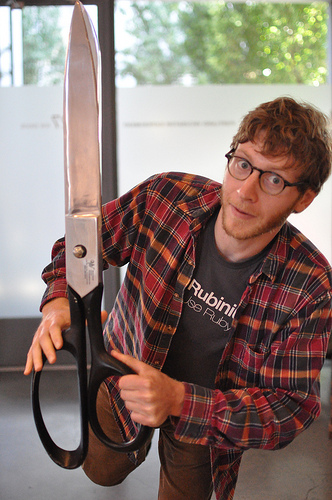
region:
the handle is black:
[26, 276, 155, 472]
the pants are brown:
[81, 368, 227, 497]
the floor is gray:
[10, 445, 60, 486]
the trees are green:
[166, 11, 314, 71]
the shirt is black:
[159, 214, 251, 396]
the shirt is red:
[95, 147, 315, 447]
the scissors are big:
[31, 2, 146, 481]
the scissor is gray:
[50, 7, 119, 305]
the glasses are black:
[210, 141, 311, 215]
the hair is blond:
[234, 78, 330, 179]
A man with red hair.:
[108, 81, 319, 497]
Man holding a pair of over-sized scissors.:
[3, 1, 329, 394]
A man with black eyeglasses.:
[201, 76, 329, 250]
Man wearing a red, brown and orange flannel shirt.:
[61, 80, 330, 424]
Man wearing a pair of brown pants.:
[58, 358, 245, 499]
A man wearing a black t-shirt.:
[115, 151, 331, 422]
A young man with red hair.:
[165, 57, 331, 239]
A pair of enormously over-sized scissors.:
[10, 0, 168, 479]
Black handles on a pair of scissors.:
[24, 273, 174, 485]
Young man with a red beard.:
[186, 76, 330, 250]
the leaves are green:
[214, 21, 299, 67]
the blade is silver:
[47, 5, 119, 311]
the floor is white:
[8, 451, 52, 488]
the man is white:
[220, 73, 325, 269]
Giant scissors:
[27, 4, 153, 480]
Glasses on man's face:
[212, 142, 290, 211]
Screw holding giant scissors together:
[70, 239, 89, 263]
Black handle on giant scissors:
[21, 275, 161, 484]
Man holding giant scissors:
[29, 81, 329, 498]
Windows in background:
[7, 3, 320, 82]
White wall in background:
[0, 86, 316, 317]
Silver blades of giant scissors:
[57, 5, 108, 285]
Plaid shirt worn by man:
[27, 162, 328, 499]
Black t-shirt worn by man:
[165, 197, 272, 439]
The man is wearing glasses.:
[220, 139, 301, 199]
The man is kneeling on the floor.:
[9, 370, 248, 499]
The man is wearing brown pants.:
[78, 374, 228, 498]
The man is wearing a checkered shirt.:
[30, 168, 331, 452]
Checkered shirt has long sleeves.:
[32, 168, 330, 453]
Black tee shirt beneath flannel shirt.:
[153, 202, 291, 411]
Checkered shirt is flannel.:
[35, 170, 330, 494]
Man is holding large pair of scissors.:
[18, 1, 164, 494]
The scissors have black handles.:
[16, 285, 159, 494]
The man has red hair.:
[223, 95, 331, 202]